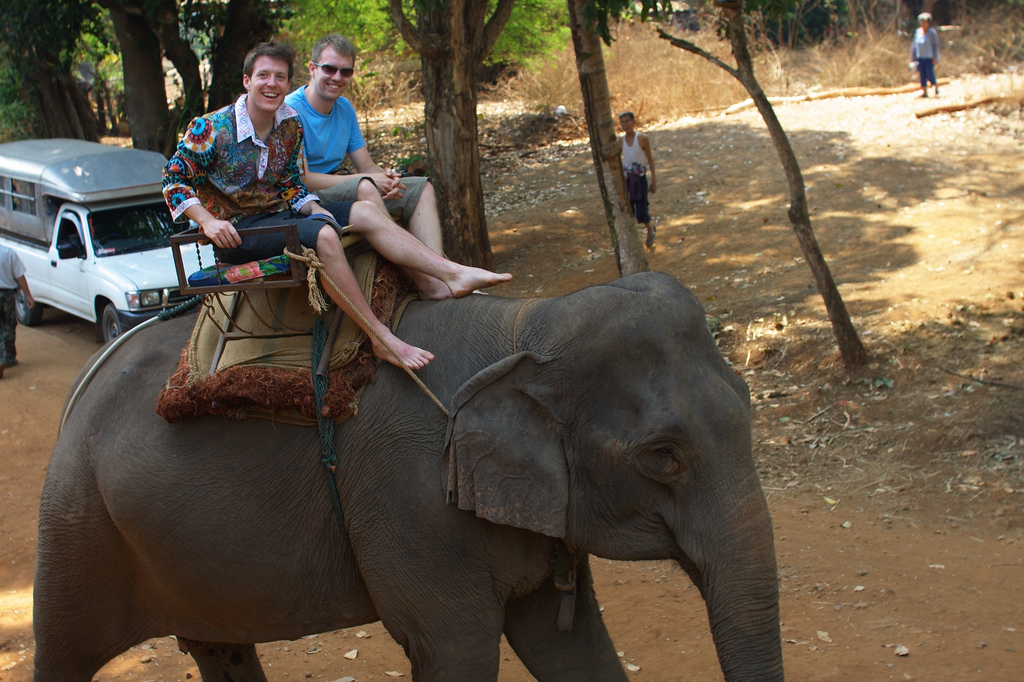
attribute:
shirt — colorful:
[154, 97, 323, 234]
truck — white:
[0, 203, 216, 346]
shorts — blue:
[198, 211, 338, 257]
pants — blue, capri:
[909, 62, 947, 94]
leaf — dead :
[816, 624, 829, 641]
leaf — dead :
[807, 479, 839, 503]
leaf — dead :
[833, 508, 847, 528]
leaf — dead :
[921, 551, 941, 565]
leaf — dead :
[763, 383, 784, 402]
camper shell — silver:
[1, 135, 170, 244]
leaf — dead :
[322, 643, 370, 669]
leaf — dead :
[343, 634, 393, 660]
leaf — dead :
[375, 666, 402, 679]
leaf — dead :
[615, 652, 654, 676]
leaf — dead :
[875, 626, 925, 657]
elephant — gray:
[30, 245, 802, 675]